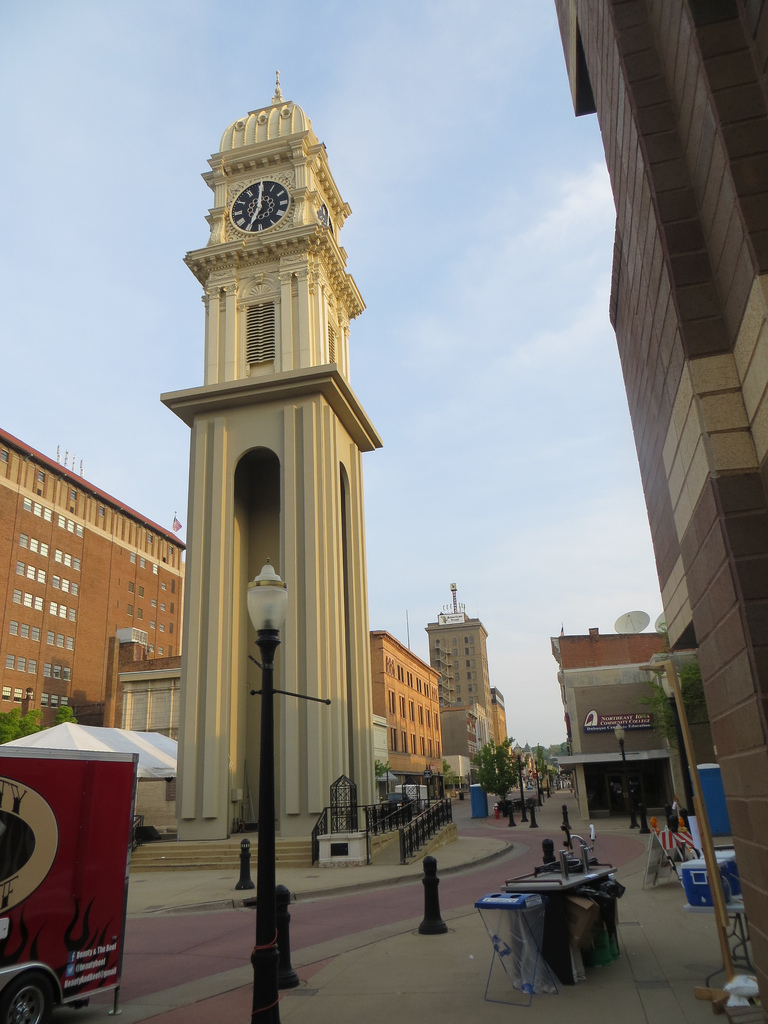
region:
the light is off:
[240, 556, 295, 643]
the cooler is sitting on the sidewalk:
[681, 857, 717, 911]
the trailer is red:
[71, 799, 120, 860]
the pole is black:
[253, 743, 284, 849]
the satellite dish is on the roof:
[612, 607, 655, 643]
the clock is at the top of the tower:
[227, 164, 302, 246]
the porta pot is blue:
[463, 778, 497, 824]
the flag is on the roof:
[166, 505, 192, 547]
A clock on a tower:
[228, 178, 291, 235]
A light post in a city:
[239, 562, 298, 1021]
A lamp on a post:
[241, 555, 295, 638]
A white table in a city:
[685, 897, 751, 986]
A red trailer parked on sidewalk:
[1, 741, 142, 1022]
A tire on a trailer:
[0, 964, 52, 1021]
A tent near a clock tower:
[0, 720, 184, 775]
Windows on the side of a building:
[7, 529, 87, 628]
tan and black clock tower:
[118, 76, 405, 826]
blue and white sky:
[375, 139, 515, 338]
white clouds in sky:
[384, 115, 568, 466]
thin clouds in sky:
[458, 190, 602, 411]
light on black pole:
[239, 556, 348, 1010]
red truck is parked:
[17, 721, 164, 1021]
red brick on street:
[160, 883, 232, 977]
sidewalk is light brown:
[315, 949, 407, 1014]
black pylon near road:
[394, 850, 457, 935]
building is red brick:
[0, 497, 171, 690]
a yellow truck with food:
[1, 745, 140, 1022]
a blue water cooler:
[676, 850, 740, 905]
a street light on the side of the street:
[610, 719, 627, 745]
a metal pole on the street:
[418, 852, 449, 935]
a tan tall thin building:
[423, 580, 496, 759]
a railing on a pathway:
[399, 792, 456, 863]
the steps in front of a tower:
[126, 843, 318, 873]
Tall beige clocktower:
[156, 64, 387, 844]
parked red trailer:
[0, 745, 141, 1022]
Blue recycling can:
[473, 889, 562, 1006]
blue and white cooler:
[677, 848, 736, 905]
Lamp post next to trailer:
[240, 553, 332, 1022]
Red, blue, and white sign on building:
[579, 708, 657, 736]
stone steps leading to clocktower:
[125, 824, 318, 876]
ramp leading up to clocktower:
[364, 792, 452, 863]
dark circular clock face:
[226, 174, 291, 236]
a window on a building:
[18, 488, 24, 512]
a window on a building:
[7, 618, 17, 634]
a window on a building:
[15, 585, 21, 602]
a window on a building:
[23, 591, 32, 607]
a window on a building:
[34, 595, 42, 611]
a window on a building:
[42, 596, 57, 608]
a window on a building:
[26, 653, 38, 673]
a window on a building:
[50, 626, 65, 653]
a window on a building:
[64, 603, 78, 623]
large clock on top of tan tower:
[224, 174, 294, 243]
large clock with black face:
[225, 173, 293, 243]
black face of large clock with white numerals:
[225, 174, 294, 238]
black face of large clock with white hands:
[224, 177, 293, 234]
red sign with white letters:
[579, 705, 657, 733]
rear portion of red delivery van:
[3, 740, 139, 1021]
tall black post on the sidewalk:
[251, 622, 290, 1021]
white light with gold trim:
[243, 558, 292, 639]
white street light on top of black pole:
[247, 557, 293, 1023]